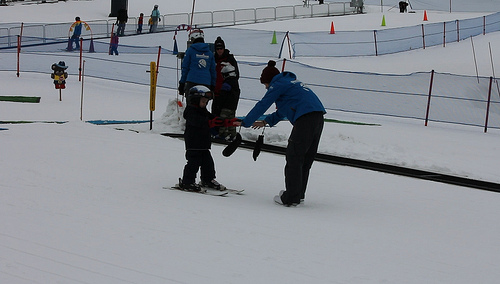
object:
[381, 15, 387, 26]
cone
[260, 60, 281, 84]
hat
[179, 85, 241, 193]
child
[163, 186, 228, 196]
skis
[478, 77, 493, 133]
poles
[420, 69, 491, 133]
fence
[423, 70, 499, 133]
row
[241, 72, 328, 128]
over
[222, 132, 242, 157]
glove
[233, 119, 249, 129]
wrist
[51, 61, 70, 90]
bear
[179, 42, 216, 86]
jacket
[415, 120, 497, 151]
snow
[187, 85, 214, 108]
helmet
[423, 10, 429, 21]
cone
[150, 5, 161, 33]
people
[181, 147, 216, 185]
pants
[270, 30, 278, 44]
cone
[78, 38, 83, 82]
posts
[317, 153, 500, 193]
railing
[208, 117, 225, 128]
gloves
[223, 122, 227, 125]
red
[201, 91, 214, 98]
googles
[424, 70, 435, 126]
pole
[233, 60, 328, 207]
people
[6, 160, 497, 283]
ground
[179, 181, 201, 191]
feet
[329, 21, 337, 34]
cones